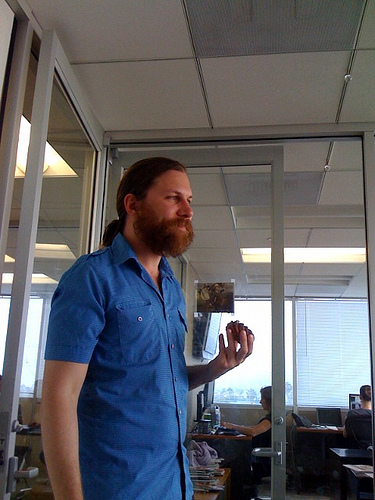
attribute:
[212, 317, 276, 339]
doughnut — mini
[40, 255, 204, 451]
shirt — blue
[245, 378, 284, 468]
woman — doing work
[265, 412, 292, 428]
lock — metal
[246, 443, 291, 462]
metal — handle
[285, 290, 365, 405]
blinds — white, horizontal blinds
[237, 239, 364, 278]
lights — white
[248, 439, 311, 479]
handle — silver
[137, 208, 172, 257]
hair — red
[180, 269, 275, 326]
photo — on glass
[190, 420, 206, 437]
pinecone — brown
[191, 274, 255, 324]
image — brown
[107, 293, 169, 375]
pocket — blue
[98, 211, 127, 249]
ponytail — thick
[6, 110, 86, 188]
lighting — fluorescent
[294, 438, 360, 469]
partition — sliding